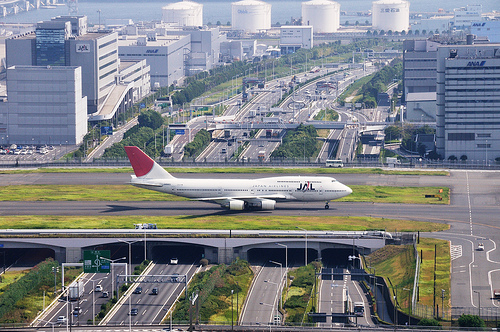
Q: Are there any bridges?
A: Yes, there is a bridge.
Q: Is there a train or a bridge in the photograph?
A: Yes, there is a bridge.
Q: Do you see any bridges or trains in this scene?
A: Yes, there is a bridge.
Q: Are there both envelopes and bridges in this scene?
A: No, there is a bridge but no envelopes.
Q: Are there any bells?
A: No, there are no bells.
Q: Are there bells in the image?
A: No, there are no bells.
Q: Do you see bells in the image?
A: No, there are no bells.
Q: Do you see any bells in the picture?
A: No, there are no bells.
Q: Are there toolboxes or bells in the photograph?
A: No, there are no bells or toolboxes.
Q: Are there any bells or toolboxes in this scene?
A: No, there are no bells or toolboxes.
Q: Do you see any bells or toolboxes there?
A: No, there are no bells or toolboxes.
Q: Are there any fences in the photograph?
A: No, there are no fences.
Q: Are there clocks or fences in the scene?
A: No, there are no fences or clocks.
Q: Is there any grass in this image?
A: Yes, there is grass.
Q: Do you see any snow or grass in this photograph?
A: Yes, there is grass.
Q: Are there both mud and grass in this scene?
A: No, there is grass but no mud.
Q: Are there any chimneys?
A: No, there are no chimneys.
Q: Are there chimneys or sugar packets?
A: No, there are no chimneys or sugar packets.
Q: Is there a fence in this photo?
A: No, there are no fences.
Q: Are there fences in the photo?
A: No, there are no fences.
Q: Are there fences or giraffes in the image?
A: No, there are no fences or giraffes.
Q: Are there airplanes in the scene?
A: Yes, there is an airplane.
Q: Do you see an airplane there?
A: Yes, there is an airplane.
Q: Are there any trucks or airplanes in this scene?
A: Yes, there is an airplane.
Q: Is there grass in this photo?
A: Yes, there is grass.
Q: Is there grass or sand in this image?
A: Yes, there is grass.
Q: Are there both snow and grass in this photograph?
A: No, there is grass but no snow.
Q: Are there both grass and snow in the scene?
A: No, there is grass but no snow.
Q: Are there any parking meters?
A: No, there are no parking meters.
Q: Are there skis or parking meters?
A: No, there are no parking meters or skis.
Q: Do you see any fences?
A: No, there are no fences.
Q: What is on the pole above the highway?
A: The sign is on the pole.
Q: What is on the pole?
A: The sign is on the pole.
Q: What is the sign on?
A: The sign is on the pole.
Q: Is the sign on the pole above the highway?
A: Yes, the sign is on the pole.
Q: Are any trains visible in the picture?
A: No, there are no trains.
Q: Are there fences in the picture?
A: No, there are no fences.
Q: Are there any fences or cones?
A: No, there are no fences or cones.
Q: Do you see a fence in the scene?
A: No, there are no fences.